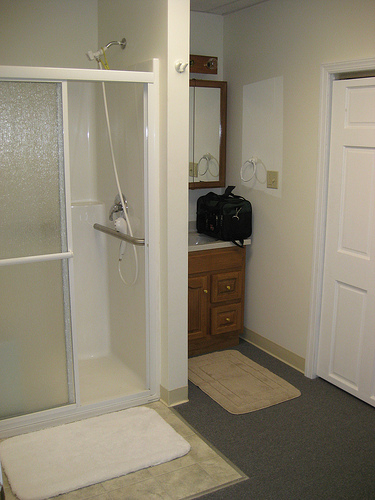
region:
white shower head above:
[70, 33, 130, 83]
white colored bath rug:
[0, 427, 217, 472]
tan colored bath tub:
[191, 338, 316, 438]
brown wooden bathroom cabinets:
[194, 253, 262, 350]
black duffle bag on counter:
[205, 193, 261, 254]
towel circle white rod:
[233, 149, 298, 212]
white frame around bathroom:
[19, 61, 170, 424]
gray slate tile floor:
[273, 430, 342, 480]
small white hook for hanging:
[172, 59, 203, 82]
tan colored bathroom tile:
[163, 456, 219, 492]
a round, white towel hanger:
[239, 157, 257, 182]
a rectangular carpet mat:
[183, 348, 301, 415]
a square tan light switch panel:
[264, 169, 280, 190]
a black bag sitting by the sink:
[194, 184, 252, 250]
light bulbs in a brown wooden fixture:
[186, 53, 219, 76]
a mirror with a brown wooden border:
[187, 78, 228, 191]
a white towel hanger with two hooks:
[173, 59, 189, 74]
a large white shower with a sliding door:
[1, 56, 160, 441]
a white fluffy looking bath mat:
[1, 403, 191, 499]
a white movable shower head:
[83, 38, 139, 287]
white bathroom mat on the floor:
[4, 408, 201, 485]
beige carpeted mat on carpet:
[184, 349, 307, 414]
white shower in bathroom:
[9, 15, 338, 496]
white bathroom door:
[297, 58, 374, 399]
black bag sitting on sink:
[194, 182, 275, 265]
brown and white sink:
[190, 231, 260, 353]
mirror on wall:
[188, 75, 228, 192]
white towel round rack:
[233, 145, 263, 199]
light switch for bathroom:
[262, 168, 288, 198]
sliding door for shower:
[0, 75, 76, 421]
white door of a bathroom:
[301, 63, 373, 395]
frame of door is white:
[305, 51, 372, 389]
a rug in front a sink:
[189, 345, 307, 424]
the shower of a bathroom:
[75, 27, 150, 292]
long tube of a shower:
[92, 60, 148, 295]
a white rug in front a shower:
[7, 402, 191, 498]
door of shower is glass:
[2, 77, 98, 424]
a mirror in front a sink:
[193, 72, 231, 186]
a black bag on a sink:
[192, 183, 262, 255]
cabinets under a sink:
[193, 261, 244, 348]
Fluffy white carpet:
[1, 380, 204, 494]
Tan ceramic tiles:
[3, 387, 250, 498]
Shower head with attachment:
[69, 24, 146, 288]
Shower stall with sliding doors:
[4, 38, 201, 457]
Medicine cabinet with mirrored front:
[171, 62, 232, 192]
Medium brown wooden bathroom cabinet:
[168, 215, 264, 349]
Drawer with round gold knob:
[212, 275, 246, 301]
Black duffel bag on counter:
[193, 167, 274, 263]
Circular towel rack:
[231, 150, 263, 191]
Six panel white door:
[309, 50, 374, 401]